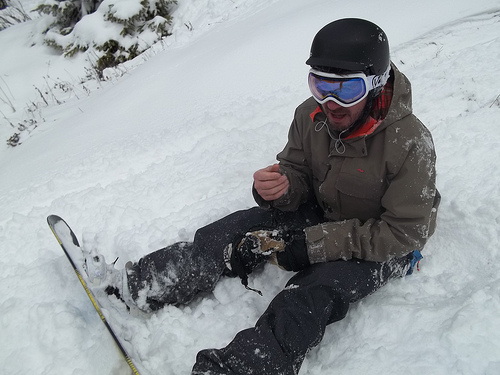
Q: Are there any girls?
A: No, there are no girls.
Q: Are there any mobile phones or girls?
A: No, there are no girls or mobile phones.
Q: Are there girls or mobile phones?
A: No, there are no girls or mobile phones.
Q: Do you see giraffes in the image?
A: No, there are no giraffes.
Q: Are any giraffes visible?
A: No, there are no giraffes.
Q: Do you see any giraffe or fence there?
A: No, there are no giraffes or fences.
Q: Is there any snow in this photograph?
A: Yes, there is snow.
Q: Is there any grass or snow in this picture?
A: Yes, there is snow.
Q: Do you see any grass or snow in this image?
A: Yes, there is snow.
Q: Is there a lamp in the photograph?
A: No, there are no lamps.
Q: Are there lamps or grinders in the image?
A: No, there are no lamps or grinders.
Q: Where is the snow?
A: The snow is on the ground.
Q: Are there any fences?
A: No, there are no fences.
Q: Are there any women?
A: No, there are no women.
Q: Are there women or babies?
A: No, there are no women or babies.